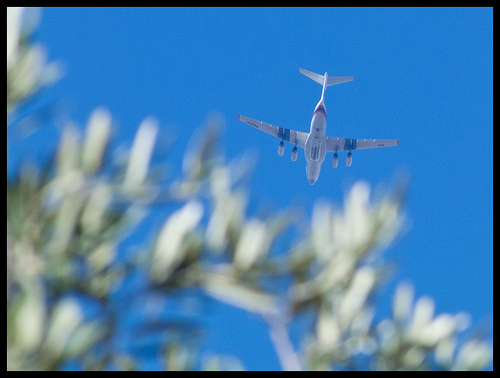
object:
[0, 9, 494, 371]
sky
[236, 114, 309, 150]
wings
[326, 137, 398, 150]
wing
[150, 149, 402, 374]
tree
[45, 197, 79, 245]
leaves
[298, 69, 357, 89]
wing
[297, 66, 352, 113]
back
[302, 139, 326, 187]
front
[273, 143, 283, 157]
fan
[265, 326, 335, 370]
branches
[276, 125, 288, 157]
engines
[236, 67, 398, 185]
jet